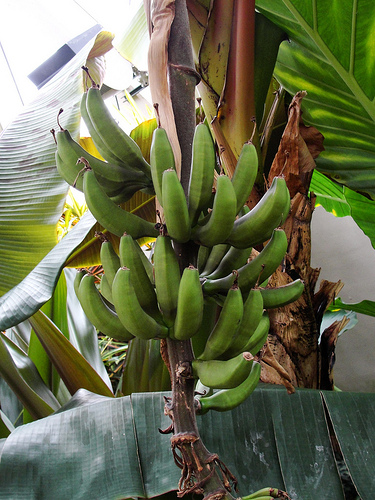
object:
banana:
[73, 156, 160, 241]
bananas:
[153, 209, 180, 319]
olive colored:
[152, 130, 219, 211]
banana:
[198, 116, 259, 227]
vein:
[349, 0, 358, 74]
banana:
[197, 269, 244, 361]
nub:
[165, 167, 175, 172]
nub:
[123, 231, 127, 236]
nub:
[187, 264, 198, 269]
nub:
[274, 175, 284, 178]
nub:
[273, 226, 283, 231]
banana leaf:
[253, 0, 375, 203]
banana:
[150, 102, 177, 208]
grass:
[98, 334, 129, 387]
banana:
[56, 107, 150, 188]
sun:
[0, 0, 92, 82]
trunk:
[208, 0, 350, 389]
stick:
[220, 0, 264, 182]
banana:
[81, 65, 151, 182]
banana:
[111, 265, 168, 343]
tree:
[0, 0, 375, 500]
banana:
[153, 209, 181, 327]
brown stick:
[158, 0, 240, 499]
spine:
[282, 0, 375, 120]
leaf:
[343, 186, 375, 249]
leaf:
[317, 295, 375, 346]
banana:
[174, 265, 205, 342]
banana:
[191, 351, 254, 390]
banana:
[221, 174, 288, 249]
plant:
[254, 0, 374, 346]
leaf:
[0, 27, 115, 297]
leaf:
[0, 116, 161, 333]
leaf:
[26, 307, 115, 397]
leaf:
[0, 332, 62, 419]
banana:
[191, 165, 238, 249]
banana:
[161, 165, 191, 244]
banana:
[188, 116, 216, 229]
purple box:
[27, 22, 104, 89]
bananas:
[261, 278, 305, 309]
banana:
[94, 230, 120, 291]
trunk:
[158, 0, 240, 500]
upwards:
[73, 209, 205, 342]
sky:
[3, 6, 37, 33]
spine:
[209, 0, 265, 191]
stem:
[158, 337, 238, 500]